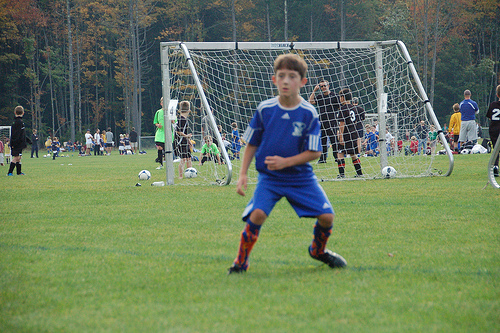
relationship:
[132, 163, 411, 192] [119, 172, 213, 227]
balls on ground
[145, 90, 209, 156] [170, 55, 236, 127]
kids by net